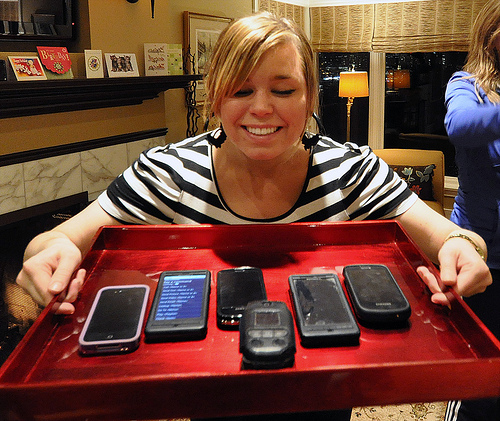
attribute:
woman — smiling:
[9, 3, 495, 421]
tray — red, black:
[2, 221, 499, 419]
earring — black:
[298, 110, 327, 150]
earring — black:
[200, 112, 225, 151]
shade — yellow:
[338, 68, 372, 99]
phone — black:
[218, 266, 264, 322]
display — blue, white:
[161, 270, 210, 329]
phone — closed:
[238, 297, 295, 372]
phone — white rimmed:
[75, 284, 153, 355]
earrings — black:
[201, 106, 324, 148]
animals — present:
[10, 37, 144, 73]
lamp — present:
[337, 68, 374, 148]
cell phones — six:
[81, 261, 407, 362]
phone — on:
[147, 264, 213, 338]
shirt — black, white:
[96, 133, 415, 222]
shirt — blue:
[447, 71, 497, 274]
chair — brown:
[370, 144, 461, 208]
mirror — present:
[2, 1, 74, 44]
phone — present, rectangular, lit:
[153, 268, 214, 341]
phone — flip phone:
[238, 301, 292, 364]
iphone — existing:
[157, 247, 236, 340]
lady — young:
[172, 0, 412, 261]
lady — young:
[120, 0, 455, 261]